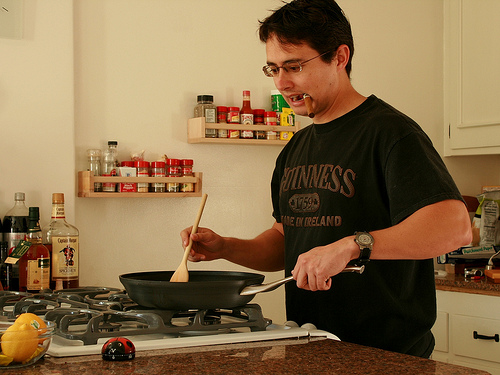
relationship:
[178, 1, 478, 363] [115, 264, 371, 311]
man holding frying pan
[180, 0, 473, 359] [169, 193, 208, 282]
man holding spoon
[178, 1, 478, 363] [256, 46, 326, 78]
man wearing eyeglasses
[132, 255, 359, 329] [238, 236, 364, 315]
frying pan with handle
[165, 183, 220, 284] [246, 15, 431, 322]
spoon held by man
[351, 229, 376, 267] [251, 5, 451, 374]
watch on man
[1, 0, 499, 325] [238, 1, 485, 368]
wall behind man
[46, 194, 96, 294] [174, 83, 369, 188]
bottle against wall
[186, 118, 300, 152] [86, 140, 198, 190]
spice rack filled with spices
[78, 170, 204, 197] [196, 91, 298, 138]
rack filled with spices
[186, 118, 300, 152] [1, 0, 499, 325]
spice rack on wall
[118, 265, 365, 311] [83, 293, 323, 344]
frying pan cooking on range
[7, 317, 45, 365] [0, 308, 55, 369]
lemons in bowl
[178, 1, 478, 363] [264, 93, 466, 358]
man wearing shirt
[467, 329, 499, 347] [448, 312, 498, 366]
handle of cabinet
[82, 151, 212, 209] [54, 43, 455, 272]
rack on wall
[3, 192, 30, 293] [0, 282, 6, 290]
bottle on counter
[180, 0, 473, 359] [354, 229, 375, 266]
man wearing watch